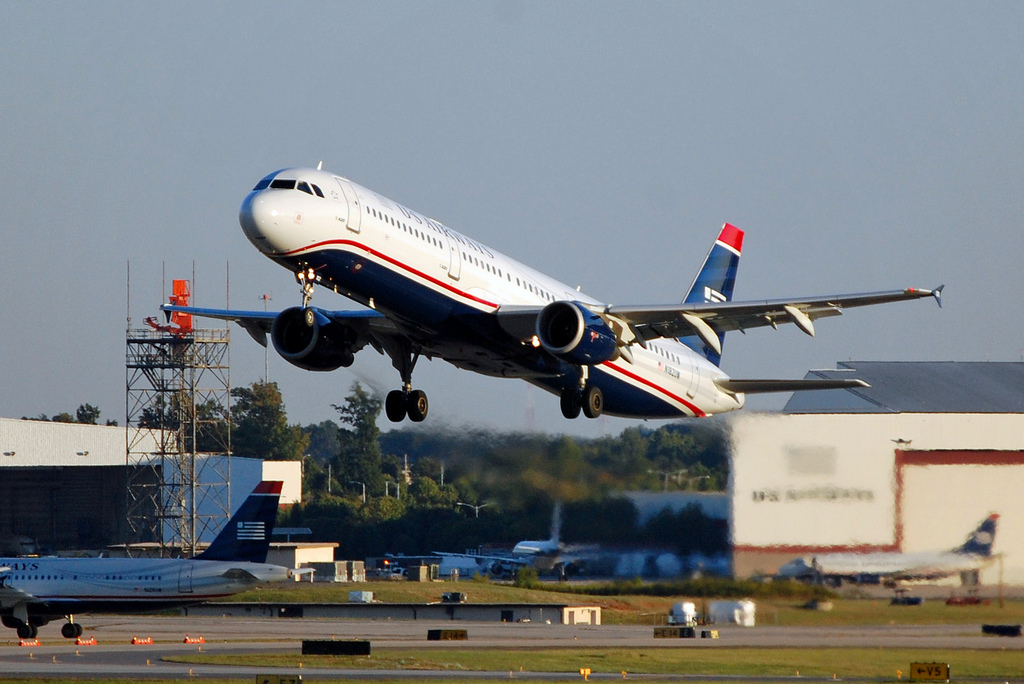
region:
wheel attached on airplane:
[380, 392, 442, 425]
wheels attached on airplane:
[276, 304, 325, 334]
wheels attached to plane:
[550, 371, 607, 419]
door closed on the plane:
[345, 181, 365, 232]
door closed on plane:
[446, 226, 460, 285]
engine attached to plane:
[540, 302, 623, 351]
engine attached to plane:
[260, 308, 349, 369]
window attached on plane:
[269, 175, 292, 196]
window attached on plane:
[297, 177, 311, 191]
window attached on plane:
[311, 180, 324, 196]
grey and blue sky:
[585, 1, 798, 202]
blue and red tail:
[605, 177, 730, 373]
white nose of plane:
[213, 180, 280, 264]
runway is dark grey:
[719, 610, 991, 645]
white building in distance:
[722, 364, 1020, 624]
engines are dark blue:
[514, 306, 636, 370]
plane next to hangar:
[769, 467, 1003, 633]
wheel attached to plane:
[556, 381, 602, 417]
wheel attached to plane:
[290, 300, 322, 333]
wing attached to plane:
[505, 283, 945, 341]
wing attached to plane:
[148, 285, 374, 325]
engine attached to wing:
[272, 305, 348, 375]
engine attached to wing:
[532, 298, 632, 374]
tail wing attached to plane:
[186, 468, 292, 558]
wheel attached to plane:
[64, 611, 83, 635]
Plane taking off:
[149, 114, 965, 497]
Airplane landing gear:
[369, 358, 610, 447]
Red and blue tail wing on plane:
[675, 211, 784, 291]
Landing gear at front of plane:
[259, 256, 349, 307]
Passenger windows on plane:
[348, 181, 571, 296]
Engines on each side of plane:
[259, 293, 613, 367]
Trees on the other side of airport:
[246, 385, 655, 538]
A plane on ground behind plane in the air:
[768, 500, 1016, 619]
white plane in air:
[169, 83, 909, 477]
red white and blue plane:
[196, 130, 947, 454]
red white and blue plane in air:
[155, 119, 947, 437]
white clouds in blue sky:
[61, 22, 172, 106]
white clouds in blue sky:
[523, 54, 616, 135]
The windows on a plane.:
[296, 179, 310, 190]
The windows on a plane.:
[310, 181, 321, 197]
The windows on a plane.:
[250, 179, 270, 189]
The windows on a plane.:
[364, 201, 374, 214]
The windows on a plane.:
[372, 209, 380, 220]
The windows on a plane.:
[378, 212, 383, 222]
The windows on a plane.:
[392, 217, 400, 230]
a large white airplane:
[241, 166, 943, 435]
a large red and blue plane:
[161, 161, 940, 427]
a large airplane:
[218, 168, 955, 426]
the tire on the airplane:
[382, 391, 444, 423]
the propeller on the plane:
[531, 301, 602, 349]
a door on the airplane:
[334, 181, 364, 224]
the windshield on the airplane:
[258, 174, 300, 193]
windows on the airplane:
[366, 208, 452, 247]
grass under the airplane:
[218, 648, 1022, 680]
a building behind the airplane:
[738, 356, 1021, 603]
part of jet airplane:
[265, 298, 358, 375]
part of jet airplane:
[370, 372, 441, 436]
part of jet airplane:
[543, 377, 605, 423]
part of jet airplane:
[530, 290, 632, 374]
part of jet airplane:
[716, 369, 871, 409]